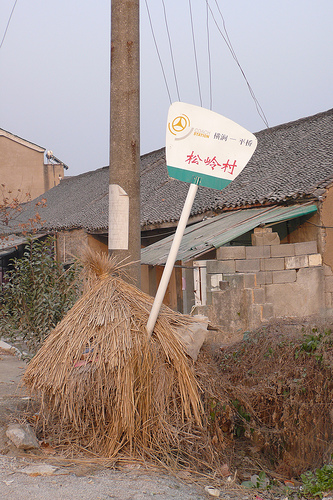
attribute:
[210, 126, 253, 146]
characters —  grey ,  sign's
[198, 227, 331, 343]
wall — bricks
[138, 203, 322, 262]
awning — green 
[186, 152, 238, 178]
characters — red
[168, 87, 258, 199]
sign — white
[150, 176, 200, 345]
pole — white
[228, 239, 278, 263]
brick — brown, gray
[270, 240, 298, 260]
brick — gray, brown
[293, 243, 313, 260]
brick — brown, gray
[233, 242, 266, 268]
brick — gray, brown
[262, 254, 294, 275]
brick — brown, gray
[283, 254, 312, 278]
brick — gray, brown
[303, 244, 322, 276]
brick — brown, gray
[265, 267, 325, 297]
brick — gray, brown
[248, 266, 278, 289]
brick — brown, gray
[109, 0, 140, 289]
post —  tall,  brown,   wooden, wooden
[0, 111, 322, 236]
roof — grey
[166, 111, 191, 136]
symbol — yellow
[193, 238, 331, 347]
wall — concrete, gray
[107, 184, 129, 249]
paper — white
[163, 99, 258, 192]
sign — gold, white, green, white, yellow, blue and red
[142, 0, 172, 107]
wire — black, electrical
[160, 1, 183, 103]
wire — black, electrical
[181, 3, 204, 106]
wire — black, electrical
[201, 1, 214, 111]
wire — black, electrical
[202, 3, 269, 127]
wire — black, electrical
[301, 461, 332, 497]
weed — green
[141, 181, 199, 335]
pole — white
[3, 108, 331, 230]
roof — grey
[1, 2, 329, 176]
sky — blue, clear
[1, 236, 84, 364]
bush — green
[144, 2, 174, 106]
wire — black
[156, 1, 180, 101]
wire — black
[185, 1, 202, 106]
wire — black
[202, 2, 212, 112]
wire — black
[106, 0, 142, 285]
pole — brown, telephone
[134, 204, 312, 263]
roof — make-shift, tin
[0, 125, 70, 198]
building — substantial, on the left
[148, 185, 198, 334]
post — white